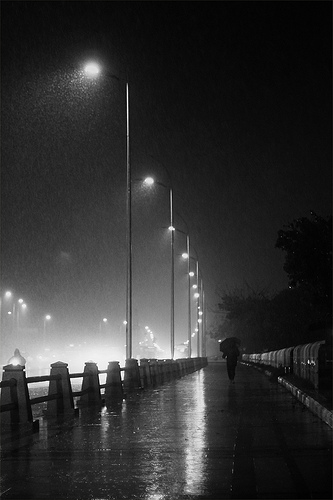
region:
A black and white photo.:
[7, 8, 325, 492]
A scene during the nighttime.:
[9, 10, 325, 491]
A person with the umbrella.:
[209, 324, 248, 387]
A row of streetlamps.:
[73, 43, 224, 373]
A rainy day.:
[44, 47, 308, 393]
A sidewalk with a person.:
[7, 340, 330, 498]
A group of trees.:
[199, 248, 331, 355]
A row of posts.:
[233, 331, 329, 397]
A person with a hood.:
[4, 342, 33, 384]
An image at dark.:
[6, 6, 328, 497]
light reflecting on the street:
[165, 394, 206, 482]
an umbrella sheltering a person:
[221, 333, 246, 347]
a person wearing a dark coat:
[226, 346, 236, 378]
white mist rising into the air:
[64, 348, 118, 365]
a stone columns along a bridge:
[66, 356, 125, 414]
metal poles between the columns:
[30, 379, 66, 406]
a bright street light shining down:
[79, 60, 106, 92]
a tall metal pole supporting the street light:
[120, 93, 124, 391]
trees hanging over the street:
[226, 292, 305, 322]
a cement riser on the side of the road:
[300, 387, 327, 409]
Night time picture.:
[31, 167, 314, 432]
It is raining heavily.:
[39, 129, 283, 472]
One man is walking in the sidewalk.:
[213, 328, 256, 401]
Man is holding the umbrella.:
[213, 333, 235, 358]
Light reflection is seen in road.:
[160, 391, 230, 497]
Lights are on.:
[2, 276, 198, 348]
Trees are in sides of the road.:
[242, 242, 321, 330]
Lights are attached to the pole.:
[157, 219, 201, 357]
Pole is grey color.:
[120, 193, 135, 358]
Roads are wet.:
[23, 372, 189, 470]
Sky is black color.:
[160, 55, 269, 166]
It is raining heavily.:
[29, 168, 288, 429]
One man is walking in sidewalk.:
[216, 337, 242, 377]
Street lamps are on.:
[117, 160, 212, 330]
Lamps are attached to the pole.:
[158, 208, 208, 355]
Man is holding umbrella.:
[213, 336, 250, 372]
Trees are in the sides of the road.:
[224, 266, 317, 340]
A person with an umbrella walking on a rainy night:
[218, 336, 243, 382]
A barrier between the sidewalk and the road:
[1, 355, 208, 451]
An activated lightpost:
[82, 60, 130, 358]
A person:
[7, 348, 26, 366]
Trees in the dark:
[205, 211, 332, 372]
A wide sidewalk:
[1, 361, 332, 498]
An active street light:
[131, 146, 174, 355]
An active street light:
[159, 199, 190, 358]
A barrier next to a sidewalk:
[206, 339, 332, 429]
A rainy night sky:
[1, 0, 332, 361]